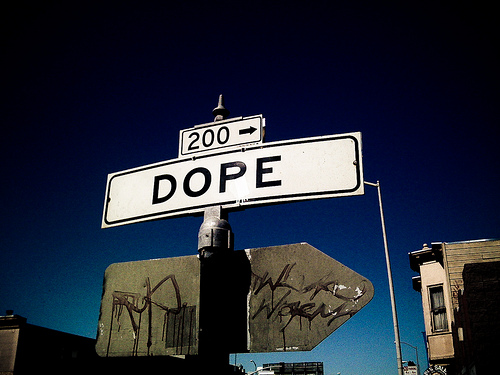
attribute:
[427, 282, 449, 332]
window — narrow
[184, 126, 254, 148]
lettering — black 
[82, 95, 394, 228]
sign — white 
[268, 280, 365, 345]
ink — dripping 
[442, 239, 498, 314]
planks — wooden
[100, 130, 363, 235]
sign — white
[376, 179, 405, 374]
pole — long , gray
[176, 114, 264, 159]
sign — black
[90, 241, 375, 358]
sign — black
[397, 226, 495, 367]
old building — old 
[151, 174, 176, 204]
black letter — black 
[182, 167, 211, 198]
black letter — black 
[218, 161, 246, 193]
black letter — black 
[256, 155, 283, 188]
black letter — black 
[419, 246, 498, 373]
fence — metal 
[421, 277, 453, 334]
window — pane 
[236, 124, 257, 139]
arrow — black 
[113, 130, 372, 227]
street sign — white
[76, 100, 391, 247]
sign — white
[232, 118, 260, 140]
arrow — black, directional 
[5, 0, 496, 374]
sky — clear , blue , getting darker, dark blue